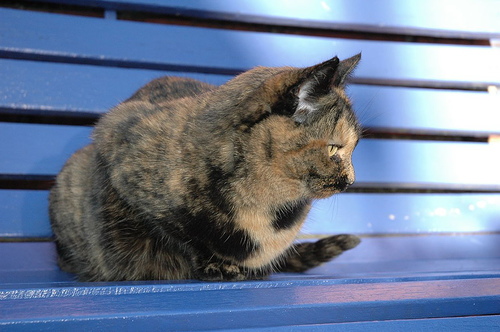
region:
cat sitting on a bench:
[21, 43, 426, 282]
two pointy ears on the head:
[288, 50, 383, 95]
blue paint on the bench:
[0, 2, 499, 327]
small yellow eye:
[325, 140, 341, 161]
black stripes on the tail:
[286, 226, 379, 270]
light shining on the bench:
[413, 12, 499, 202]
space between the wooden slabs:
[1, 173, 70, 189]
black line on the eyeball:
[326, 140, 338, 152]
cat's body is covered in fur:
[50, 45, 378, 285]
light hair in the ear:
[294, 80, 312, 110]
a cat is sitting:
[51, 52, 361, 277]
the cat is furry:
[50, 55, 362, 284]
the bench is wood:
[2, 0, 499, 330]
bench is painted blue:
[0, 0, 498, 330]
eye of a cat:
[325, 140, 338, 157]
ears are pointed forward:
[291, 52, 361, 116]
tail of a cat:
[277, 235, 361, 272]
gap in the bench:
[0, 108, 102, 125]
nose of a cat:
[340, 169, 354, 183]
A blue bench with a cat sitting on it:
[0, 1, 499, 328]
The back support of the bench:
[1, 1, 497, 278]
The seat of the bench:
[1, 257, 499, 329]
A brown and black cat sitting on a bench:
[48, 52, 363, 281]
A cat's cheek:
[308, 179, 324, 194]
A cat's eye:
[326, 142, 338, 155]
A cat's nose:
[346, 165, 354, 185]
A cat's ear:
[292, 54, 340, 119]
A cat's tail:
[278, 232, 359, 272]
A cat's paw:
[201, 260, 241, 280]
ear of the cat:
[277, 49, 322, 114]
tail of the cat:
[248, 233, 357, 277]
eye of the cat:
[320, 144, 347, 161]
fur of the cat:
[80, 222, 163, 259]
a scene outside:
[5, 5, 490, 323]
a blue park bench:
[5, 1, 495, 328]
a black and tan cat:
[38, 45, 363, 298]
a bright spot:
[330, 0, 496, 242]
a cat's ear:
[287, 50, 347, 126]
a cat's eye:
[315, 135, 347, 160]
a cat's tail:
[267, 223, 367, 278]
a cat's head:
[225, 41, 377, 211]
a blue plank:
[4, 5, 498, 85]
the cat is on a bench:
[1, 3, 426, 300]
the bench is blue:
[1, 1, 490, 329]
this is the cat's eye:
[322, 135, 339, 157]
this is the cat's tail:
[287, 222, 377, 285]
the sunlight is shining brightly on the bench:
[341, 13, 496, 223]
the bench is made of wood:
[4, 5, 499, 328]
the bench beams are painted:
[0, 0, 498, 325]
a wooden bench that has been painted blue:
[2, 0, 497, 325]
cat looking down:
[47, 48, 371, 285]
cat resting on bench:
[43, 46, 368, 286]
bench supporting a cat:
[0, 0, 499, 329]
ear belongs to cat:
[287, 55, 340, 110]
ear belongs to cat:
[332, 51, 364, 86]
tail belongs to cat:
[269, 230, 364, 274]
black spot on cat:
[267, 192, 313, 232]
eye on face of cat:
[322, 140, 343, 159]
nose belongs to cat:
[339, 167, 357, 189]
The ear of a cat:
[288, 53, 339, 113]